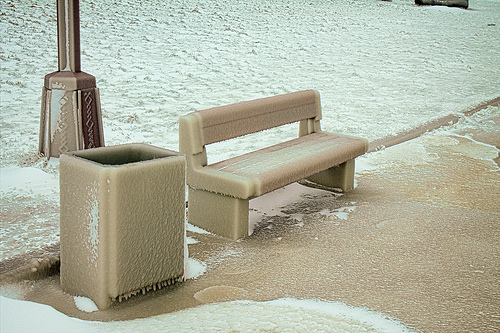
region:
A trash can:
[48, 134, 198, 304]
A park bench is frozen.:
[180, 91, 385, 238]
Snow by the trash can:
[53, 290, 118, 325]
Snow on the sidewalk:
[190, 294, 447, 331]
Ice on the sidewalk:
[467, 129, 499, 196]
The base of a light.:
[36, 70, 113, 165]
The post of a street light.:
[50, 0, 89, 70]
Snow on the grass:
[134, 9, 353, 73]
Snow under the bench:
[242, 182, 326, 214]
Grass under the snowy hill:
[148, 8, 316, 63]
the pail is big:
[52, 137, 192, 314]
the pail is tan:
[54, 136, 190, 316]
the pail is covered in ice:
[48, 140, 198, 309]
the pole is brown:
[39, 20, 105, 131]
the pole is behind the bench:
[25, 16, 107, 127]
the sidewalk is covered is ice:
[395, 181, 481, 302]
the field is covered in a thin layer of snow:
[302, 18, 453, 78]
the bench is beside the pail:
[60, 129, 191, 299]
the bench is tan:
[174, 63, 392, 239]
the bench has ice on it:
[230, 150, 287, 179]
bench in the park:
[155, 81, 395, 253]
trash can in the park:
[76, 113, 196, 331]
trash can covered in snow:
[49, 135, 246, 326]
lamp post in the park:
[22, 0, 137, 203]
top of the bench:
[163, 87, 357, 143]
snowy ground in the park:
[79, 21, 468, 152]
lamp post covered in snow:
[20, 1, 135, 171]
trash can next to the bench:
[37, 137, 482, 315]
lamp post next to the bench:
[44, 1, 395, 297]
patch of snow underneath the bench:
[226, 175, 341, 232]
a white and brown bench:
[176, 87, 371, 242]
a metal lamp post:
[52, 0, 88, 75]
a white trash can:
[53, 136, 195, 311]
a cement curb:
[2, 92, 497, 284]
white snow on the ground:
[0, 0, 499, 260]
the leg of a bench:
[182, 185, 259, 245]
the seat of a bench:
[203, 119, 371, 202]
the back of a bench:
[175, 85, 330, 150]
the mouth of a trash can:
[68, 135, 182, 185]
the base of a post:
[17, 67, 114, 167]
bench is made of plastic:
[179, 102, 413, 247]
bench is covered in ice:
[202, 94, 371, 227]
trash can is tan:
[47, 110, 217, 327]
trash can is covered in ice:
[50, 124, 209, 331]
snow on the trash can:
[77, 191, 118, 251]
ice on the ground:
[280, 221, 480, 314]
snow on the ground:
[166, 21, 350, 63]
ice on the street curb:
[13, 255, 84, 312]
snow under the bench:
[237, 177, 346, 221]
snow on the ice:
[211, 313, 299, 325]